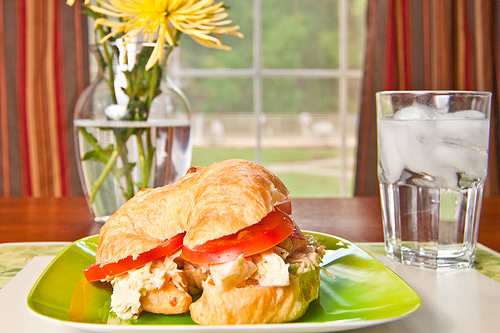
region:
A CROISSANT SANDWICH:
[81, 154, 326, 329]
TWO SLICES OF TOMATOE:
[81, 206, 301, 284]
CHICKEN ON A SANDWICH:
[106, 227, 326, 319]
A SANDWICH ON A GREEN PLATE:
[25, 154, 424, 330]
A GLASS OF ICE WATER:
[371, 83, 498, 274]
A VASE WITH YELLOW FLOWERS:
[59, 3, 249, 227]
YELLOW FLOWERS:
[63, 1, 248, 72]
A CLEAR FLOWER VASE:
[69, 40, 194, 222]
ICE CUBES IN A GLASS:
[371, 101, 498, 191]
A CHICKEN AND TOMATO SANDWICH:
[79, 155, 329, 331]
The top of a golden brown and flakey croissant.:
[89, 159, 298, 259]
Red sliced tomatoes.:
[75, 200, 296, 280]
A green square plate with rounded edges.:
[24, 222, 423, 327]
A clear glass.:
[376, 87, 491, 274]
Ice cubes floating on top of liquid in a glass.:
[383, 104, 488, 185]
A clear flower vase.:
[72, 42, 192, 222]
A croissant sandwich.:
[86, 156, 325, 324]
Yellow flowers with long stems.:
[59, 0, 246, 200]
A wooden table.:
[1, 194, 498, 247]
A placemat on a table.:
[0, 240, 496, 327]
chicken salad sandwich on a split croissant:
[88, 156, 332, 326]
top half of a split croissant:
[92, 158, 286, 262]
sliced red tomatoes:
[77, 199, 300, 280]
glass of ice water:
[371, 86, 496, 271]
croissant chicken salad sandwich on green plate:
[26, 159, 425, 329]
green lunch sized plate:
[26, 229, 421, 328]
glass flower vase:
[66, 40, 196, 230]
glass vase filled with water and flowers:
[64, 0, 229, 222]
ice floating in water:
[372, 105, 493, 195]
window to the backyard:
[86, 0, 367, 198]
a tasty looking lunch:
[22, 88, 494, 330]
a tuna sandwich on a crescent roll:
[80, 153, 325, 324]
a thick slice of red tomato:
[176, 215, 296, 261]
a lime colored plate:
[30, 228, 421, 328]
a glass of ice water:
[374, 87, 491, 269]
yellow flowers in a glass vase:
[63, 1, 242, 218]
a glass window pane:
[259, 2, 341, 71]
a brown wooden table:
[0, 191, 497, 251]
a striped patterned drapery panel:
[0, 0, 87, 200]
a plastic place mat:
[0, 240, 498, 331]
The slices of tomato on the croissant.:
[92, 229, 295, 264]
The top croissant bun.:
[91, 176, 271, 239]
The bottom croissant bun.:
[139, 266, 324, 316]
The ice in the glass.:
[379, 102, 479, 191]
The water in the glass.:
[377, 99, 482, 255]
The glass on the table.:
[377, 73, 485, 268]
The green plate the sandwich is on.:
[39, 235, 394, 324]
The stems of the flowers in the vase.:
[80, 57, 157, 189]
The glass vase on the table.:
[82, 41, 182, 201]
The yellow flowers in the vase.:
[104, 6, 229, 48]